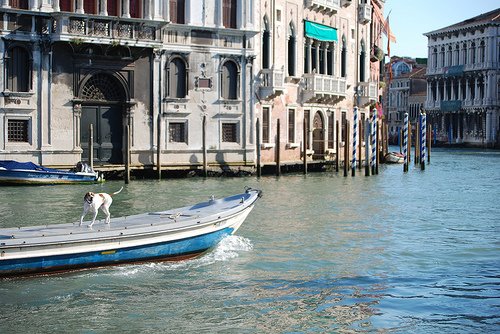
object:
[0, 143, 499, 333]
canal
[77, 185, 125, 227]
dog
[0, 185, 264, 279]
boat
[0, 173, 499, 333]
water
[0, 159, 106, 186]
boat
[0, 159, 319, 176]
dock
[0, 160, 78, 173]
tarp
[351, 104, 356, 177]
pole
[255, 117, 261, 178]
poles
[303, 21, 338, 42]
awning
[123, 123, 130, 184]
poles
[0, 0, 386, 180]
building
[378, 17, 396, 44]
flag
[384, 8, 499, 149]
building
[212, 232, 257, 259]
wave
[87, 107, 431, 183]
fence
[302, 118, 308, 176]
pole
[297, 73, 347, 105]
balcony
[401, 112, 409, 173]
post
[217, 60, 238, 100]
window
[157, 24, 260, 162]
wall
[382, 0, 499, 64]
sky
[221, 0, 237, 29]
windows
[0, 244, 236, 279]
bottom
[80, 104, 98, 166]
doors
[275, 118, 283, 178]
post